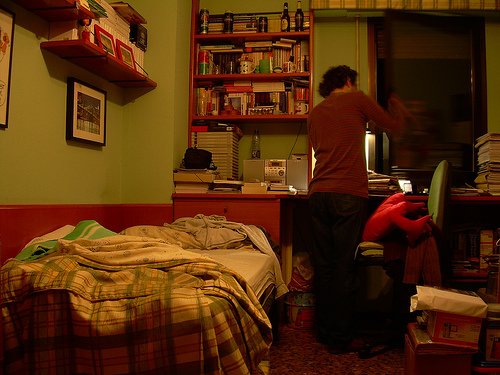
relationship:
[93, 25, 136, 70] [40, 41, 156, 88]
frames on shelf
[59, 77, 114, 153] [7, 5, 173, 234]
picture on wall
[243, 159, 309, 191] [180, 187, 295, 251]
speakers on table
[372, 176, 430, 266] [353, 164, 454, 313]
pillow on chair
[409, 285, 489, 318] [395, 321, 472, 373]
paper on box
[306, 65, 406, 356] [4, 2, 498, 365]
boy standing in bedroom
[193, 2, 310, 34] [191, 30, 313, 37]
beet bottles on shelf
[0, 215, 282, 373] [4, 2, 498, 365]
bed in bedroom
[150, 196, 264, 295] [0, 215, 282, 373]
pants on bed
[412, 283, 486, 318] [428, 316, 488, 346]
paper on box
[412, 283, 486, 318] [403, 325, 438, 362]
paper on box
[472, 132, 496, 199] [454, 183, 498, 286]
books on table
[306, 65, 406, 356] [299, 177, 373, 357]
boy wearing jeans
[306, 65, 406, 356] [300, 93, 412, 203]
boy wearing shirt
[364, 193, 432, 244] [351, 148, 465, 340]
pillow on chair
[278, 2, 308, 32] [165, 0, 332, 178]
bottles on shelf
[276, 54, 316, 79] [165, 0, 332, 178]
cans on shelf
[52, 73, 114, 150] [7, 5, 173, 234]
artwork on wall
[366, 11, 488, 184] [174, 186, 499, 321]
window above desk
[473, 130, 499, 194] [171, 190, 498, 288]
books on desk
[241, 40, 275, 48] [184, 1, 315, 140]
book on shelf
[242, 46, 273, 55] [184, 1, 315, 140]
book on shelf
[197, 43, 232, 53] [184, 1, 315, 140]
book on shelf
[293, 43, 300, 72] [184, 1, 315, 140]
book on shelf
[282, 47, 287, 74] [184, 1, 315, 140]
book on shelf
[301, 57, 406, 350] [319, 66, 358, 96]
boy has brown hair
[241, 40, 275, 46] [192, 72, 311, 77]
book on shelf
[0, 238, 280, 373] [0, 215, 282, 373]
bedspread foot of bed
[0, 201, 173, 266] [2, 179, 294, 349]
paneling bottom of wall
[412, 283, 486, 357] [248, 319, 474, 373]
boxes stacked on floor